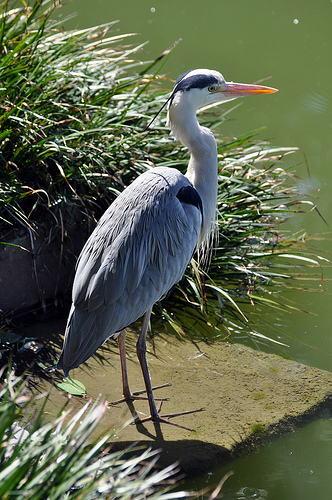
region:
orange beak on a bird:
[228, 80, 281, 99]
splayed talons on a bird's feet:
[110, 383, 206, 441]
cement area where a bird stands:
[189, 338, 320, 436]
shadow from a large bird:
[103, 416, 226, 499]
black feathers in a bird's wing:
[171, 174, 209, 229]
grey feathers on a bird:
[81, 277, 134, 326]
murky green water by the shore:
[267, 448, 316, 499]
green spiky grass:
[10, 390, 133, 497]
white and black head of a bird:
[174, 65, 209, 111]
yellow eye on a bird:
[207, 82, 216, 92]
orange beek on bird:
[219, 80, 278, 96]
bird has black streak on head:
[168, 68, 219, 99]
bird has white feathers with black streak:
[57, 165, 203, 378]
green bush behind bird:
[0, 0, 330, 355]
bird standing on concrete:
[6, 314, 330, 485]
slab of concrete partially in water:
[3, 325, 330, 477]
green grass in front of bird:
[1, 361, 233, 498]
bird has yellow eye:
[207, 84, 218, 92]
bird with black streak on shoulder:
[177, 185, 204, 228]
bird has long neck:
[172, 112, 216, 271]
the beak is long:
[219, 68, 285, 113]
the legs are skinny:
[97, 313, 193, 432]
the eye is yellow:
[202, 82, 220, 95]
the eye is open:
[202, 76, 223, 101]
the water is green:
[260, 418, 317, 492]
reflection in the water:
[217, 476, 279, 498]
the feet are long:
[113, 369, 210, 451]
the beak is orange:
[216, 78, 280, 98]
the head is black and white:
[165, 64, 221, 92]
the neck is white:
[163, 100, 225, 189]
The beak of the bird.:
[230, 84, 276, 96]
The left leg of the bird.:
[117, 333, 130, 396]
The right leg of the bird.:
[139, 318, 165, 442]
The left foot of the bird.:
[116, 386, 171, 402]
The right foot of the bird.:
[136, 405, 194, 427]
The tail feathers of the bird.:
[55, 314, 101, 370]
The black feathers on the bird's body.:
[173, 185, 209, 218]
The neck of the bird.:
[170, 106, 219, 195]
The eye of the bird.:
[208, 85, 215, 91]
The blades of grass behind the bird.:
[11, 10, 302, 347]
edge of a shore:
[243, 420, 281, 471]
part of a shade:
[193, 438, 223, 461]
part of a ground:
[237, 390, 254, 408]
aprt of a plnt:
[132, 452, 145, 469]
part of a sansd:
[206, 399, 224, 428]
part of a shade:
[194, 444, 217, 492]